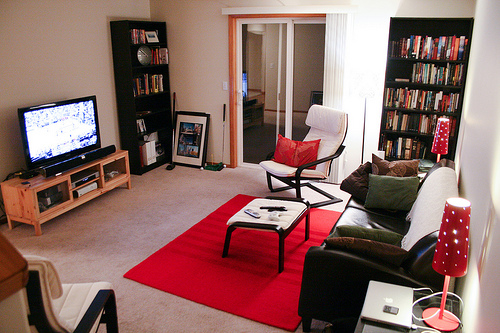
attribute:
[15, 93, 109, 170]
tv — big, operating, sitting, flat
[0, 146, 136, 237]
stand — wooden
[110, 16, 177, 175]
bookshelf — dark, black, full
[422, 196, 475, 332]
lamp — sitting, red, standing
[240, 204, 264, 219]
remote — sitting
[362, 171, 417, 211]
pillow — green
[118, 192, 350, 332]
rug — red, laying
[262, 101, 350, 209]
chair — white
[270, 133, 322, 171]
pillow — red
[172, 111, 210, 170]
picture — leaning, framed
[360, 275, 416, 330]
laptop — silver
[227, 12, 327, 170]
doorframe — brown